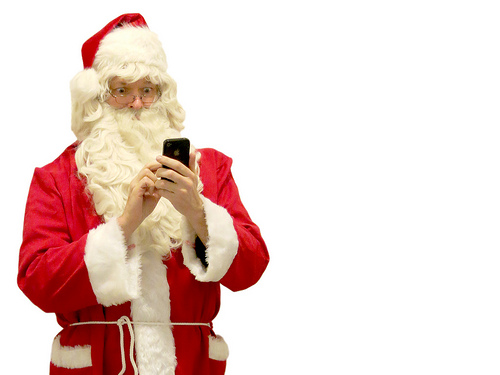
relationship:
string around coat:
[112, 308, 139, 374] [20, 140, 242, 367]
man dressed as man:
[18, 13, 274, 373] [18, 13, 274, 373]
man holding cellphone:
[18, 13, 269, 373] [162, 138, 188, 185]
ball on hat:
[68, 68, 101, 100] [68, 11, 167, 101]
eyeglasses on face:
[103, 84, 165, 104] [90, 62, 181, 159]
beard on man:
[72, 99, 188, 260] [18, 13, 274, 373]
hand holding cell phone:
[150, 152, 201, 217] [160, 137, 191, 184]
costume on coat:
[16, 12, 269, 373] [18, 138, 268, 373]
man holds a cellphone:
[18, 13, 274, 373] [160, 134, 189, 189]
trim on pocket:
[201, 337, 228, 362] [51, 332, 93, 374]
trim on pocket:
[201, 337, 228, 362] [200, 326, 228, 372]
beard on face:
[80, 99, 188, 259] [99, 70, 169, 109]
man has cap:
[18, 13, 274, 373] [71, 0, 193, 90]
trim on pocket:
[201, 337, 228, 362] [187, 325, 229, 373]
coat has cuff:
[18, 138, 268, 373] [85, 216, 143, 309]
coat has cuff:
[18, 138, 268, 373] [181, 195, 238, 282]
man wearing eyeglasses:
[18, 13, 274, 373] [89, 77, 176, 112]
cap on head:
[78, 11, 174, 76] [54, 12, 192, 131]